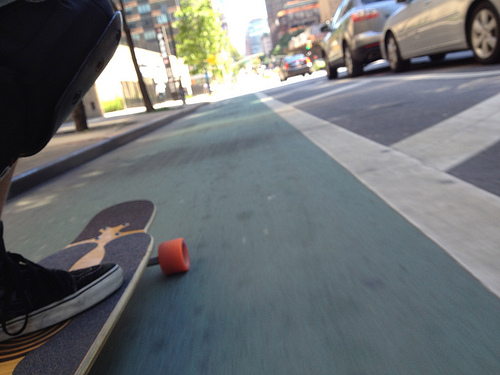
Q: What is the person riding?
A: A skateboard.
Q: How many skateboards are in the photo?
A: One.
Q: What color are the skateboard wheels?
A: Orange.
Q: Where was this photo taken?
A: On a city street.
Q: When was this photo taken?
A: In the daytime.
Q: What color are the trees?
A: Green.